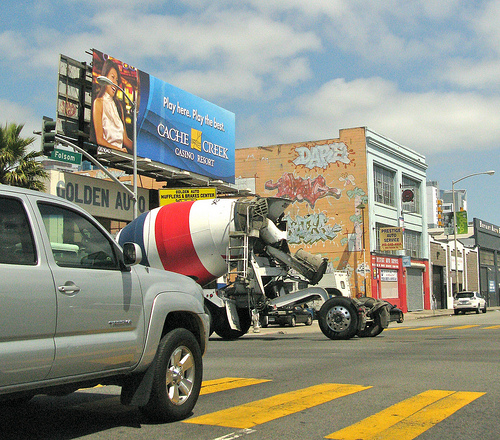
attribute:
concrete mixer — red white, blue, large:
[113, 193, 402, 339]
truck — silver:
[1, 182, 208, 419]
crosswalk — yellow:
[180, 364, 497, 439]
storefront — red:
[370, 252, 431, 315]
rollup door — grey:
[406, 265, 425, 310]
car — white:
[454, 290, 489, 312]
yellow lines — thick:
[200, 375, 486, 439]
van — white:
[450, 287, 488, 318]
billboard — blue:
[59, 47, 240, 184]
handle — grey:
[58, 278, 80, 296]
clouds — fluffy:
[296, 76, 499, 153]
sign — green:
[444, 208, 471, 236]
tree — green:
[0, 122, 49, 188]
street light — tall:
[450, 170, 494, 318]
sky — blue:
[4, 0, 495, 81]